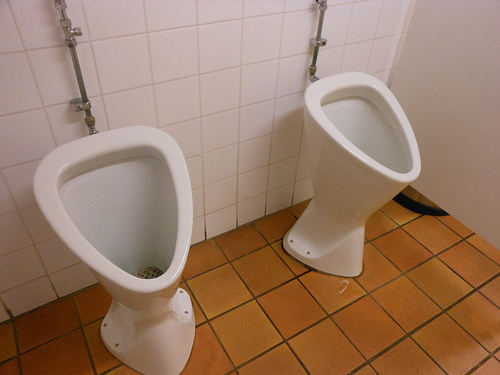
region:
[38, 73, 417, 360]
two urinals in a bathroom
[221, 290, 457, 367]
square tiles on the bathroom floor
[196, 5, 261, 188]
white tiles on the bathroom wall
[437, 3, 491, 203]
white bathroom stall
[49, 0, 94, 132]
silver pipe attached to the urinal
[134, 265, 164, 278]
silver drain in the urinal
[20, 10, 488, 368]
scene of an indoor restroom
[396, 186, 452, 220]
black and silver trashcan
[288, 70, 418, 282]
white bathroom urinal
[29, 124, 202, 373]
white urinal closest to the camera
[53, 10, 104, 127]
a metal pole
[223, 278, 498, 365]
a brown tile floor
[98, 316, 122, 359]
a pair of screws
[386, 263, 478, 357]
some brown grout between tiles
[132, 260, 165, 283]
a stainless steel drain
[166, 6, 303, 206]
a white tile wall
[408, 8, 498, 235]
a plain white stall wall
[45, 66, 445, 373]
a pair of urinals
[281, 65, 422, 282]
a white porcelain urinal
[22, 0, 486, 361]
a public restroom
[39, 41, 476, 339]
a public urinal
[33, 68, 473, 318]
public white bathroom urinals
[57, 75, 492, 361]
two public bathroom urinals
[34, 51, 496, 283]
urinals that are public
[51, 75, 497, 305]
urinals in a bathroom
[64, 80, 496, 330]
urinals that are white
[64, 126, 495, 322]
urinals in a public bathroom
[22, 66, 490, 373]
two urinals that are white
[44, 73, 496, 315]
two white urinals in the bathroom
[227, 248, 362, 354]
the floor is brown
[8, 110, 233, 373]
the toilet is white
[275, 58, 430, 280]
the toilet is white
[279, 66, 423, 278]
A white porcelin urinal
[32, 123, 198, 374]
A white porcelin urinal bolted to the floor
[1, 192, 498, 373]
A dark brown tiled floor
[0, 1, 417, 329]
A white tiled wall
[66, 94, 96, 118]
A chrome wall bracket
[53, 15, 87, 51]
A chrome flush valve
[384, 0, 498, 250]
A white wall divider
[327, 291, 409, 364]
A single brown floor tile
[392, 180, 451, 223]
The bottom of silver garbage can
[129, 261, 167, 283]
The drain at the bottom of urinal